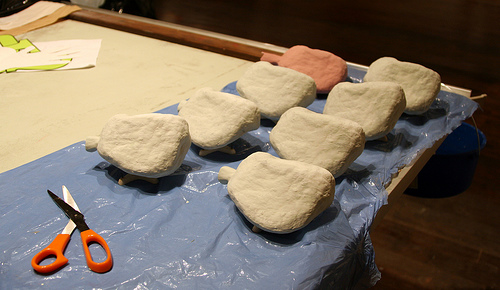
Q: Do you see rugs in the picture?
A: No, there are no rugs.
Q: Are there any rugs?
A: No, there are no rugs.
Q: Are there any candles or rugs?
A: No, there are no rugs or candles.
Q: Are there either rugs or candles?
A: No, there are no rugs or candles.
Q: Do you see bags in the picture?
A: Yes, there is a bag.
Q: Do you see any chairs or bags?
A: Yes, there is a bag.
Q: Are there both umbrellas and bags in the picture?
A: No, there is a bag but no umbrellas.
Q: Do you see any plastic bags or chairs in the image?
A: Yes, there is a plastic bag.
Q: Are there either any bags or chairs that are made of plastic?
A: Yes, the bag is made of plastic.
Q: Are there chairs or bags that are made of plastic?
A: Yes, the bag is made of plastic.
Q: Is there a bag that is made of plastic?
A: Yes, there is a bag that is made of plastic.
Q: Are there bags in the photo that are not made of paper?
A: Yes, there is a bag that is made of plastic.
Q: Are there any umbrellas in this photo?
A: No, there are no umbrellas.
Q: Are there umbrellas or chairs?
A: No, there are no umbrellas or chairs.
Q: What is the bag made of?
A: The bag is made of plastic.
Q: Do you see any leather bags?
A: No, there is a bag but it is made of plastic.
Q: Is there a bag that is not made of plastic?
A: No, there is a bag but it is made of plastic.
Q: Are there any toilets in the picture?
A: No, there are no toilets.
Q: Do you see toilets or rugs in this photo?
A: No, there are no toilets or rugs.